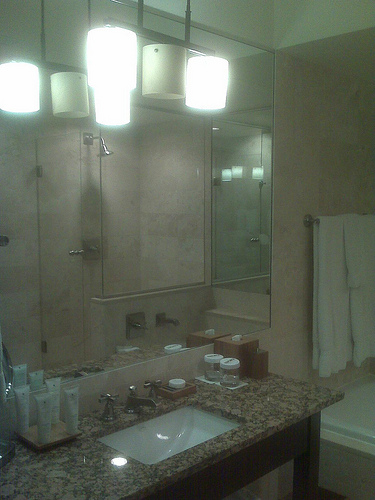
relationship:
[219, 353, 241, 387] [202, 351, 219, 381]
glass jar in front of glass jar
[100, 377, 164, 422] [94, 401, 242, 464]
faucet over sink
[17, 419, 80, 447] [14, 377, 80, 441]
plate holding tubes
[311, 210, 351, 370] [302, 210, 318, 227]
towel are hanging on bar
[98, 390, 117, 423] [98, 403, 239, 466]
knob on a sink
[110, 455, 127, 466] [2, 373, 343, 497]
spot on counter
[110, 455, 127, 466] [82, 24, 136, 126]
spot from light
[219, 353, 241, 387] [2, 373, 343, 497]
glass jar are on counter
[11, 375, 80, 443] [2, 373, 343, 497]
bottles are on counter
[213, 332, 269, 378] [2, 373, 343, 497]
tissue box on counter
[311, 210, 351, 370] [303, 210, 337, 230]
towel hang on rack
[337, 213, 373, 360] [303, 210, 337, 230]
towel hang on rack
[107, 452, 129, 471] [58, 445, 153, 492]
light reflected onto counter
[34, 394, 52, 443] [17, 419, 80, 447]
container on a plate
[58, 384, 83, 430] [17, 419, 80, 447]
container on a plate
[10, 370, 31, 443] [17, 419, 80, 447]
bottles on a plate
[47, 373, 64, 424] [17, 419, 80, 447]
container on a plate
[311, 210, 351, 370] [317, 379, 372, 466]
towel hanging over bathtub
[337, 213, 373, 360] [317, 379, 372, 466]
towel hanging over bathtub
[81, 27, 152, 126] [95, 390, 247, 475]
bathroom lights hanging over sink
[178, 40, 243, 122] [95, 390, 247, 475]
light hanging over sink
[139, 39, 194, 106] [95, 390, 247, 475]
light hanging over sink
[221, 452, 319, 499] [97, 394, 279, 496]
cabinet under sink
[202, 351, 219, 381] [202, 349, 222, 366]
glass jar with lid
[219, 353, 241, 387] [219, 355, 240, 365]
glass jar with lid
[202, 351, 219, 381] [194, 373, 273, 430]
glass jar on counter